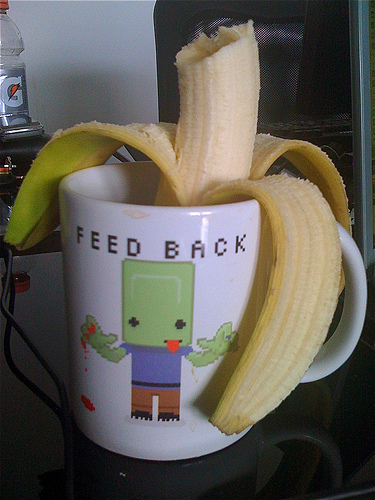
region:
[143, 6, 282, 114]
yellow banana in a cup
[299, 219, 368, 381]
handle of the cup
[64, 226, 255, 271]
words on the cup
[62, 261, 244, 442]
figure on the cup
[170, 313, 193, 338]
eye of the figure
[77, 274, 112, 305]
white background of cup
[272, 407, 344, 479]
reflection of the cup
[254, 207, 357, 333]
peel of the banana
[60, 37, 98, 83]
white wall in the background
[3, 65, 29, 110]
the letter G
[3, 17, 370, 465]
peeled banana in coffee cup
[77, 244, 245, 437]
green monster on front of coffee cup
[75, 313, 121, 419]
blood dripping from green monster hand on coffee cup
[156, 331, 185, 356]
red tongue on green monster on front of white coffee cup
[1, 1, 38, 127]
empty clear bottle of gatorade with orange cap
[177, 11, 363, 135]
black mesh lumbar support on back of chair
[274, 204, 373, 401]
white handle on coffee mug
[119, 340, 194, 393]
purple shirt on green monster on coffee cup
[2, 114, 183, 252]
green and yellow banana peel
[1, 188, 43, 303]
reflection of gatorade bottle with orange cap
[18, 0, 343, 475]
the banana is in a mug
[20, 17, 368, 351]
the banana has been peeled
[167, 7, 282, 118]
someone bit the banana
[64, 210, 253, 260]
the words say "feed back"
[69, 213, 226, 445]
there is a cartoon zombie on the mug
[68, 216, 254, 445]
a cartoon video game zombie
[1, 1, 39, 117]
empty bottle of gatorade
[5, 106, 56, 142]
a cell phone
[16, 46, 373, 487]
the mug is on a black desk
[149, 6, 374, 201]
the back rest of a black chair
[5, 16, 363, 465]
a whtie coffee mug with banana in it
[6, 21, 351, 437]
a peeled and bitten banana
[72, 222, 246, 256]
"Feed Back," written on coffee cup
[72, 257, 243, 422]
a green skin monster printed on coffee cup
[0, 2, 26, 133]
an empty Gatorade bottle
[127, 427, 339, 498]
reflection of coffee cup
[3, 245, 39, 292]
reflection of Gatorade bottle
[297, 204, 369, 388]
a white round coffee cup handle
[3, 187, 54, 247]
green peel on banana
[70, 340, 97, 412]
a blood drip design on coffee cup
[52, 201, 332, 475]
coffee mug on counter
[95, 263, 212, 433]
monster on coffee mug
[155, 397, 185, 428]
leg of the monster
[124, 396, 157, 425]
leg of the monster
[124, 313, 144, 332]
eye of the monster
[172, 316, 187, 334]
eye of the monster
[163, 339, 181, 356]
tongue of the monster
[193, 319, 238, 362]
hand of the monster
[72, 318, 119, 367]
hand of the monster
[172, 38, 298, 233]
banana in a coffee mug